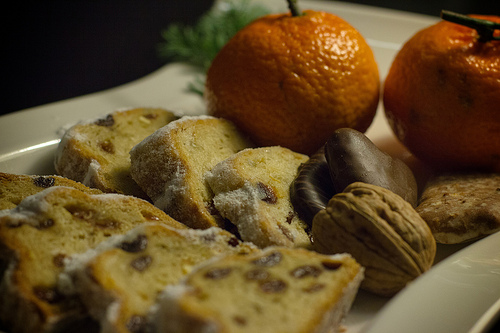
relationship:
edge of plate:
[470, 292, 498, 326] [354, 243, 496, 320]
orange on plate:
[201, 0, 381, 156] [0, 0, 496, 332]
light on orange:
[296, 23, 359, 78] [207, 10, 380, 148]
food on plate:
[12, 19, 372, 304] [61, 42, 477, 312]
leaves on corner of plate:
[163, 56, 216, 125] [30, 30, 480, 326]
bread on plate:
[4, 108, 371, 327] [0, 0, 496, 332]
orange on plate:
[381, 12, 498, 173] [0, 0, 496, 332]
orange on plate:
[207, 10, 380, 148] [0, 0, 496, 332]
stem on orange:
[286, 0, 306, 17] [235, 19, 406, 106]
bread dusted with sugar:
[0, 107, 366, 333] [147, 105, 221, 128]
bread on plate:
[0, 107, 366, 333] [0, 0, 496, 332]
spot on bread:
[116, 227, 157, 280] [58, 220, 261, 331]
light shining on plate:
[0, 136, 68, 171] [0, 0, 496, 332]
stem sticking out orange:
[283, 1, 303, 18] [201, 14, 373, 147]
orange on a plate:
[207, 10, 380, 148] [0, 0, 496, 332]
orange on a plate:
[381, 12, 498, 173] [0, 0, 496, 332]